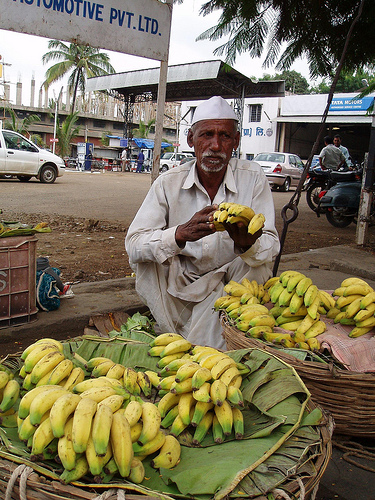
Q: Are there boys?
A: No, there are no boys.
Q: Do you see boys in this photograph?
A: No, there are no boys.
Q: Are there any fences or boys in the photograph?
A: No, there are no boys or fences.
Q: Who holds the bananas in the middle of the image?
A: The man holds the bananas.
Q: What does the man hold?
A: The man holds the bananas.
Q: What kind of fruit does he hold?
A: The man holds the bananas.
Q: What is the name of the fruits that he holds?
A: The fruits are bananas.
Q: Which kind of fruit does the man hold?
A: The man holds the bananas.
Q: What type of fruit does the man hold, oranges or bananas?
A: The man holds bananas.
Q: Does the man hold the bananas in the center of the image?
A: Yes, the man holds the bananas.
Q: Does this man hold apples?
A: No, the man holds the bananas.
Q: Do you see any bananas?
A: Yes, there are bananas.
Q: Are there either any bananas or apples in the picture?
A: Yes, there are bananas.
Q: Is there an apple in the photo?
A: No, there are no apples.